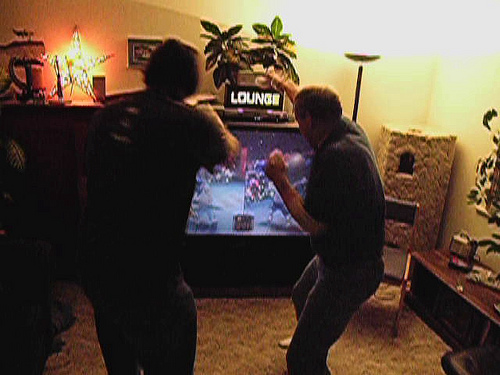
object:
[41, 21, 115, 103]
star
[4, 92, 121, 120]
shelf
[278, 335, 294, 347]
sock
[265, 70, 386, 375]
man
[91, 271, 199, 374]
pants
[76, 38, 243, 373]
man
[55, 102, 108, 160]
wii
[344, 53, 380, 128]
lamp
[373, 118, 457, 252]
tower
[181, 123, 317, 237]
television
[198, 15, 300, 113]
potted plant